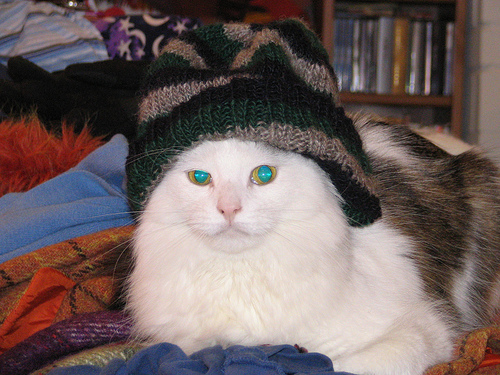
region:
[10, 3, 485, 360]
Cat with green eyes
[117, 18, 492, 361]
Cat wearing knit hat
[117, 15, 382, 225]
Green, tan and white hat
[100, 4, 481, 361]
Cat sitting near bookcase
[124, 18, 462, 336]
Car wearing hat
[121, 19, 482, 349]
Green eyed cat wearing hat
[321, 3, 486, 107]
Books lined on shelf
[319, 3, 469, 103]
Bookcase holding books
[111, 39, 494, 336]
Cat with white, brown and gray fur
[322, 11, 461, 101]
Row of books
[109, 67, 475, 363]
white cat is wearing rasta beanie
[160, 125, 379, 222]
Eyes on the cat.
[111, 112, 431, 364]
White cat on the bed.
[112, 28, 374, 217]
Hat on the white cat.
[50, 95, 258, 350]
Blankets under the cat.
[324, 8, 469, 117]
Books in the shelves.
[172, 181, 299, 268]
Nose of the cat.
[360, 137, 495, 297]
Brown on the white cat.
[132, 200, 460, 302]
Whiskers on the cat.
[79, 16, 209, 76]
White and purple blanket.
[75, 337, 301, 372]
Blue blanket in front of the cat.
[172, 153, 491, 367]
the cat is white and grey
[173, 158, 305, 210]
the eyes are blue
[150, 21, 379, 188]
the marvin is blue and grey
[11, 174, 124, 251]
the towel is blue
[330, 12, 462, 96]
there are books on the shelf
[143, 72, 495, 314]
the cat is on the bed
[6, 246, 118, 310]
the blanket is brown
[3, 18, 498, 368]
the cat is indoors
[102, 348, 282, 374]
the clothing is blue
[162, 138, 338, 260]
the eye pupil is oval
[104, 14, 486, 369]
white cat wearing hat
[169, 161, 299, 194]
blue and yellow eyes of a cat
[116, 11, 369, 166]
striped hat on top of cat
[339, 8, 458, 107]
books on a bookshelf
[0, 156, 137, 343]
pile of clothes on bed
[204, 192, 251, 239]
pink nose and mouth of a cat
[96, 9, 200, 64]
purple and white star clothes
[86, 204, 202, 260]
whickers of a cat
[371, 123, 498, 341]
back side of a cat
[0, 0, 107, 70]
blue and black striped shirt